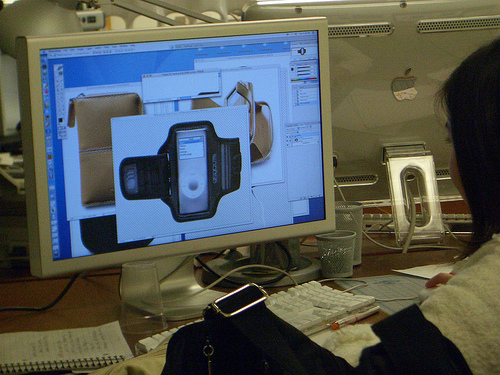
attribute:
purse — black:
[157, 274, 375, 374]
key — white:
[308, 301, 334, 323]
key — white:
[327, 302, 351, 319]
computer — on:
[23, 34, 392, 332]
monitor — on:
[1, 31, 359, 234]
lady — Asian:
[179, 98, 499, 370]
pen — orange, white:
[283, 285, 401, 348]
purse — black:
[128, 287, 337, 372]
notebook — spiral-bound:
[6, 284, 149, 371]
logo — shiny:
[383, 71, 421, 118]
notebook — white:
[19, 296, 148, 372]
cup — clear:
[114, 260, 174, 363]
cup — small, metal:
[317, 198, 377, 296]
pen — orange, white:
[317, 304, 384, 331]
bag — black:
[199, 274, 328, 372]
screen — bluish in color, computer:
[15, 10, 340, 283]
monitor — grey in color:
[15, 11, 340, 324]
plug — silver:
[71, 6, 107, 32]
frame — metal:
[21, 40, 343, 289]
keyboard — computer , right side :
[123, 264, 372, 370]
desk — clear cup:
[40, 253, 451, 369]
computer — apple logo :
[27, 11, 353, 281]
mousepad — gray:
[323, 256, 418, 310]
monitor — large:
[11, 13, 360, 277]